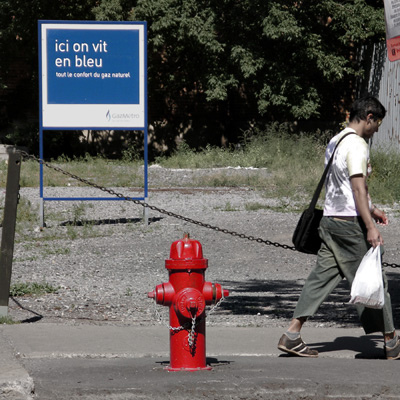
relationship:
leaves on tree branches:
[330, 58, 345, 66] [308, 35, 355, 85]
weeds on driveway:
[53, 224, 118, 242] [2, 185, 400, 328]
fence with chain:
[4, 140, 400, 344] [24, 147, 400, 276]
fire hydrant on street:
[149, 230, 229, 369] [25, 357, 399, 399]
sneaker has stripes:
[279, 338, 318, 358] [290, 341, 305, 352]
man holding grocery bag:
[282, 92, 400, 363] [355, 243, 386, 312]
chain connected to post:
[24, 147, 400, 276] [2, 150, 19, 309]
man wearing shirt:
[282, 92, 400, 363] [323, 126, 371, 218]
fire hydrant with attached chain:
[149, 230, 229, 369] [155, 295, 227, 347]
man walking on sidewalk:
[282, 92, 400, 363] [6, 321, 400, 359]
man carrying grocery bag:
[282, 92, 400, 363] [355, 243, 386, 312]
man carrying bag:
[282, 92, 400, 363] [298, 210, 321, 250]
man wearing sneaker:
[282, 92, 400, 363] [279, 338, 318, 358]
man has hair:
[282, 92, 400, 363] [347, 96, 384, 119]